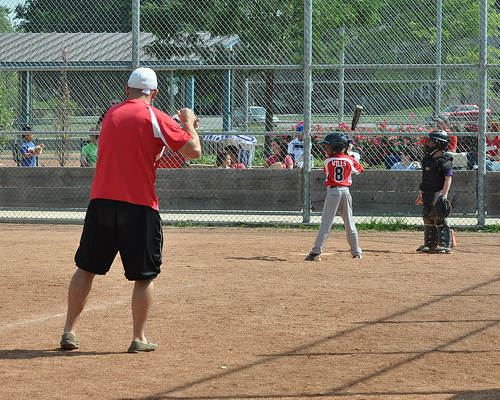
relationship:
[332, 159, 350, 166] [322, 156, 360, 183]
name on jersey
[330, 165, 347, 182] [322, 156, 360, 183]
number on jersey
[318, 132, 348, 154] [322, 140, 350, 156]
cap on head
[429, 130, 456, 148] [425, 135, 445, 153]
helmet on head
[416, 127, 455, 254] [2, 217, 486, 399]
catcher on field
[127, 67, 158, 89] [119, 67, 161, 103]
cap on head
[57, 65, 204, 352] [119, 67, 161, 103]
man has head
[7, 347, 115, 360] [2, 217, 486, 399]
shadow on field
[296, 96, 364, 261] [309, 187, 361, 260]
batter has pants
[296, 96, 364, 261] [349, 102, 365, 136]
batter holding bat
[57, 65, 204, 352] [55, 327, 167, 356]
man wears shoes